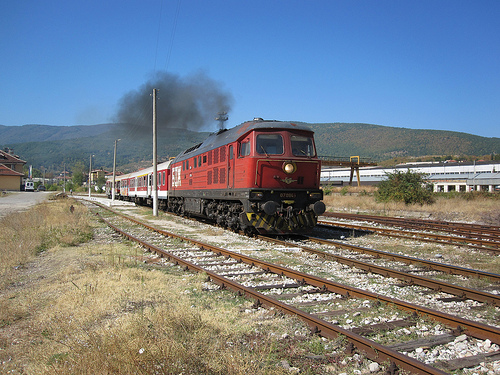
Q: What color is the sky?
A: Blue.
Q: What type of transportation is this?
A: Train.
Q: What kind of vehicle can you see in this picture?
A: Train.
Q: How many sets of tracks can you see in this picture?
A: 4.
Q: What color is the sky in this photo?
A: Blue.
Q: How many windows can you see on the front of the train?
A: 2.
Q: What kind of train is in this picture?
A: Diesel.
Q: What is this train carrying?
A: Passengers.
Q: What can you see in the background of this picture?
A: Mountains.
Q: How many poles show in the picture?
A: Three.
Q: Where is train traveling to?
A: Towards right.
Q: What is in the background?
A: Mountains.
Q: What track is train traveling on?
A: Second track.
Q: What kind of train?
A: Old passenger train.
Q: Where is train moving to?
A: Ahead to destination.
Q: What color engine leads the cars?
A: Red.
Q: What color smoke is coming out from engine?
A: Black.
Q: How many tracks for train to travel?
A: Four.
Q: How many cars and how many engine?
A: 3 cars and 1 engine.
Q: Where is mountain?
A: Behind train.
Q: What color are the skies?
A: Blue.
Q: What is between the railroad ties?
A: Rocks.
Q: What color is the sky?
A: Blue.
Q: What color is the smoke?
A: Black.